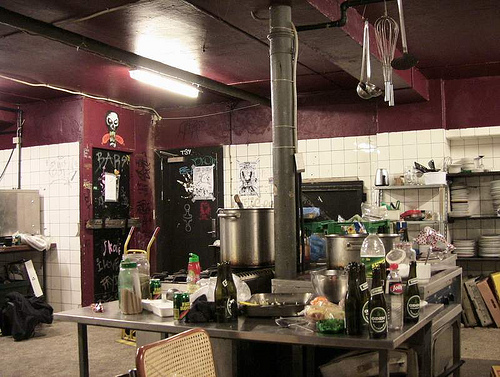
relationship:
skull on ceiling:
[77, 96, 170, 160] [59, 55, 208, 172]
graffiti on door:
[99, 149, 146, 204] [84, 149, 220, 240]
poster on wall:
[181, 153, 233, 225] [39, 147, 98, 220]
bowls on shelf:
[445, 184, 499, 217] [423, 163, 499, 232]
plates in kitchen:
[444, 194, 491, 255] [3, 113, 407, 373]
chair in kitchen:
[122, 321, 237, 365] [3, 113, 407, 373]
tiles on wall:
[42, 143, 112, 198] [39, 147, 98, 220]